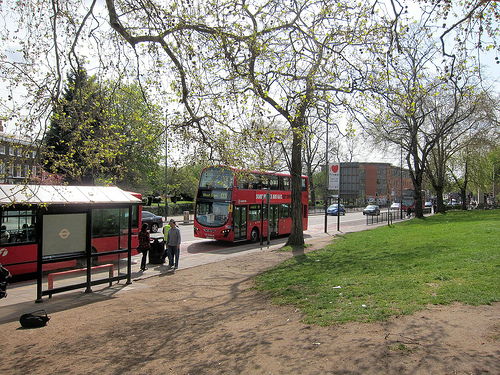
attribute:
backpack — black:
[13, 309, 59, 336]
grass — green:
[251, 211, 497, 322]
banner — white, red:
[327, 164, 342, 193]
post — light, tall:
[319, 103, 331, 236]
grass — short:
[259, 205, 498, 320]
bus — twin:
[188, 163, 312, 242]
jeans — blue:
[159, 243, 204, 269]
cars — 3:
[326, 199, 398, 214]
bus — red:
[165, 116, 347, 251]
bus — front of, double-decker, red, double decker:
[190, 161, 312, 250]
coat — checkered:
[138, 230, 155, 252]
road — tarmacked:
[0, 207, 412, 312]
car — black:
[359, 202, 384, 222]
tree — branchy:
[263, 78, 323, 229]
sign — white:
[323, 162, 345, 193]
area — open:
[264, 209, 498, 312]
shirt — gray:
[165, 227, 177, 245]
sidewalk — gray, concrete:
[4, 242, 280, 265]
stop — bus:
[2, 178, 146, 300]